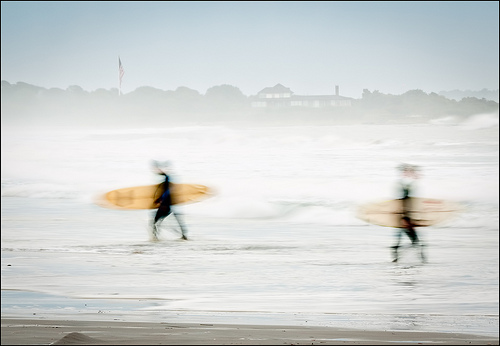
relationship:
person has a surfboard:
[149, 155, 189, 243] [99, 178, 214, 212]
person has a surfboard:
[389, 179, 430, 268] [349, 193, 457, 230]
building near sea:
[246, 81, 353, 120] [9, 113, 500, 332]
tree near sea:
[202, 80, 249, 117] [9, 113, 500, 332]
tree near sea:
[0, 80, 499, 121] [9, 113, 500, 332]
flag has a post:
[117, 58, 127, 83] [116, 56, 122, 104]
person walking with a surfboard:
[149, 155, 189, 243] [99, 178, 214, 212]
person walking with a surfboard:
[389, 179, 430, 268] [349, 193, 457, 230]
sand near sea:
[1, 309, 499, 344] [9, 113, 500, 332]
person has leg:
[149, 155, 189, 243] [154, 207, 165, 242]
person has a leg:
[149, 155, 189, 243] [171, 210, 190, 243]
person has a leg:
[389, 179, 430, 268] [390, 230, 404, 262]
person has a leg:
[389, 179, 430, 268] [404, 227, 428, 265]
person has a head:
[149, 155, 189, 243] [150, 158, 169, 182]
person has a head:
[389, 179, 430, 268] [392, 171, 420, 192]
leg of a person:
[154, 207, 165, 242] [149, 155, 189, 243]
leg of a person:
[171, 210, 190, 243] [149, 155, 189, 243]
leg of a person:
[390, 230, 404, 262] [389, 179, 430, 268]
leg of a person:
[404, 227, 428, 265] [389, 179, 430, 268]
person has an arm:
[149, 155, 189, 243] [150, 182, 162, 198]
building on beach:
[246, 81, 353, 120] [16, 110, 464, 137]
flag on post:
[117, 58, 127, 83] [116, 56, 122, 104]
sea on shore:
[9, 113, 500, 332] [2, 278, 499, 344]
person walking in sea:
[149, 155, 189, 243] [9, 113, 500, 332]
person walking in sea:
[389, 179, 430, 268] [9, 113, 500, 332]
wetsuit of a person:
[150, 172, 186, 232] [149, 155, 189, 243]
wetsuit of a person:
[395, 188, 423, 250] [389, 179, 430, 268]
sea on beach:
[9, 113, 500, 332] [16, 110, 464, 137]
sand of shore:
[1, 309, 499, 344] [2, 278, 499, 344]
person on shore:
[149, 155, 189, 243] [2, 278, 499, 344]